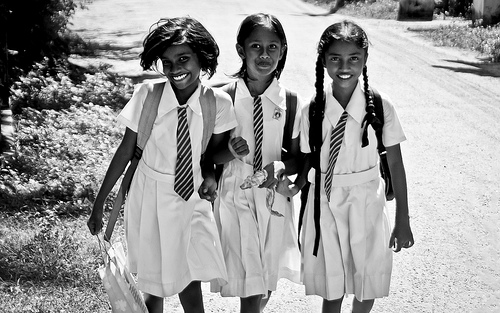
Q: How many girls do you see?
A: Three.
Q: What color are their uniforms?
A: White.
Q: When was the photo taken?
A: Daytime.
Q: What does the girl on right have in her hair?
A: Braids.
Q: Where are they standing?
A: Side of road.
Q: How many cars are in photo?
A: None.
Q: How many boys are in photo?
A: No boys.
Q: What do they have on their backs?
A: Backpacks.